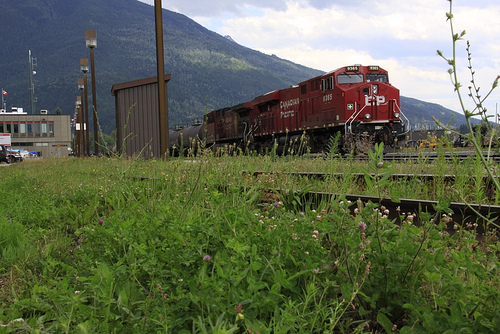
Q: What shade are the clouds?
A: Gray and white.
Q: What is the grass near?
A: Train tracks.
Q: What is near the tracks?
A: Grass.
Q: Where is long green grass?
A: Near train tracks.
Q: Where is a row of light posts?
A: Near train tracks.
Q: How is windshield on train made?
A: Two windows.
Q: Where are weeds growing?
A: Near train tracks.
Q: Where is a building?
A: Left side.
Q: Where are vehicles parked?
A: Near building.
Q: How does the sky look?
A: Blue with white clouds.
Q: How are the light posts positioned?
A: In a row.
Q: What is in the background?
A: A mountain.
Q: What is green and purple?
A: Weeds.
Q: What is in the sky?
A: Clouds.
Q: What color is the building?
A: Grey.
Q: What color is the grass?
A: Green.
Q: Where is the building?
A: On the left.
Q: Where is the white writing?
A: On the train.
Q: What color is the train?
A: Red.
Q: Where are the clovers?
A: In the grass.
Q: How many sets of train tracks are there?
A: Two.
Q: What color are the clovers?
A: Pink.